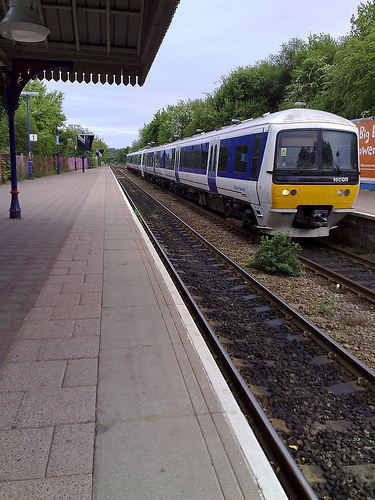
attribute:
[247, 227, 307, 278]
bush — green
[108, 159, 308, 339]
tracks — iron, railroad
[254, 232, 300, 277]
bush — small 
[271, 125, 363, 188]
windshield — glass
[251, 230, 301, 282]
bush — little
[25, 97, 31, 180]
pole — light, slender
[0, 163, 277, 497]
platform — loading, brick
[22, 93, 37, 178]
light pole — metal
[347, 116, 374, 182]
sign — orange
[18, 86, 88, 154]
trees — green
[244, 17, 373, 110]
trees — green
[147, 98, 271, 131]
trees — green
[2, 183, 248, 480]
pavement — gray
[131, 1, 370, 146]
trees — green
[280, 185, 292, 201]
headlight — round 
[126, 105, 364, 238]
train — long, mostly white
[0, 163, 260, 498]
pavement — stone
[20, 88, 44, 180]
lamp post — blue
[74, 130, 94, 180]
lamp post — train 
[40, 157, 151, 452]
balcony — train station